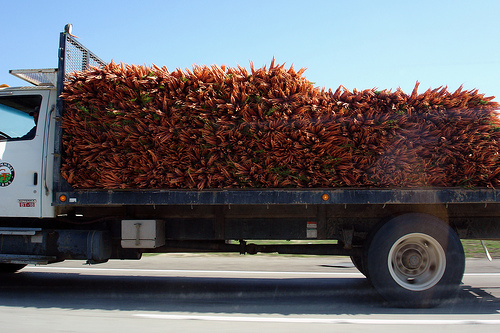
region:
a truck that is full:
[65, 33, 390, 206]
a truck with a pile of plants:
[109, 67, 366, 206]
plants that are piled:
[144, 56, 429, 161]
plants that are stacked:
[164, 66, 474, 250]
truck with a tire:
[373, 194, 487, 316]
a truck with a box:
[114, 211, 170, 252]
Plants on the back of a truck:
[62, 64, 498, 189]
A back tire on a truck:
[369, 214, 464, 308]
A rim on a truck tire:
[385, 235, 442, 291]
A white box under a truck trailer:
[118, 219, 168, 248]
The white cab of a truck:
[3, 83, 67, 276]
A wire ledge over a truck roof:
[10, 65, 57, 84]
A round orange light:
[317, 189, 329, 201]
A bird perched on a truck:
[59, 20, 81, 42]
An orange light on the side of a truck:
[51, 190, 68, 204]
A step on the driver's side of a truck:
[3, 228, 50, 268]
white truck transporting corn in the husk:
[2, 7, 499, 292]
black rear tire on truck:
[373, 221, 460, 297]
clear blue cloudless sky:
[8, 0, 498, 92]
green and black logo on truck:
[0, 155, 15, 188]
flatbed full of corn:
[63, 47, 499, 221]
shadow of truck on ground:
[8, 250, 498, 319]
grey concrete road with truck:
[5, 255, 499, 327]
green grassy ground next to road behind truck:
[168, 245, 498, 262]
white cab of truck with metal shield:
[6, 33, 108, 270]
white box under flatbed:
[118, 213, 162, 254]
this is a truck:
[5, 22, 498, 302]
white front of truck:
[3, 58, 63, 232]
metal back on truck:
[31, 20, 102, 225]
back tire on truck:
[363, 212, 470, 314]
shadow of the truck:
[20, 243, 492, 330]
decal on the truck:
[3, 157, 20, 206]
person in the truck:
[8, 70, 43, 160]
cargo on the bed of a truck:
[64, 55, 497, 185]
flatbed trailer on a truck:
[52, 179, 498, 219]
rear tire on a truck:
[359, 213, 470, 313]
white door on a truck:
[1, 88, 48, 218]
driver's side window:
[1, 91, 43, 147]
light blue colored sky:
[1, 0, 499, 108]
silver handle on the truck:
[43, 103, 53, 203]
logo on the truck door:
[0, 156, 15, 189]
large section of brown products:
[203, 93, 280, 139]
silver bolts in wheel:
[398, 238, 440, 280]